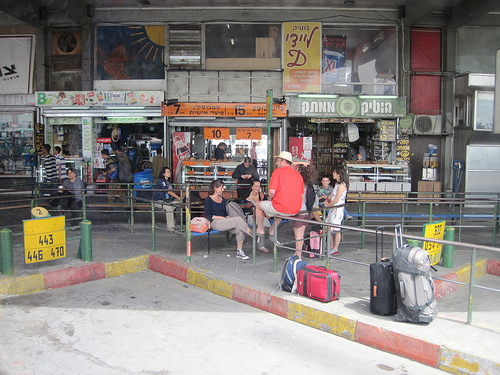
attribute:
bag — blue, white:
[277, 254, 305, 295]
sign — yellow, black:
[2, 204, 96, 271]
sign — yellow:
[22, 203, 87, 271]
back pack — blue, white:
[281, 251, 306, 296]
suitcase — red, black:
[274, 241, 367, 316]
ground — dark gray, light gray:
[342, 167, 406, 217]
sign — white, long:
[36, 90, 165, 112]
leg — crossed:
[212, 217, 257, 239]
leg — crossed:
[230, 225, 249, 257]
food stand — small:
[161, 98, 294, 197]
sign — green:
[288, 96, 405, 118]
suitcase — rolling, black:
[368, 242, 405, 316]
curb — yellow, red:
[3, 254, 497, 374]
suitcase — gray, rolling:
[390, 221, 444, 330]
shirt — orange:
[226, 143, 313, 243]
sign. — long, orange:
[279, 15, 331, 103]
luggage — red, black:
[294, 260, 346, 304]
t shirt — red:
[265, 171, 348, 249]